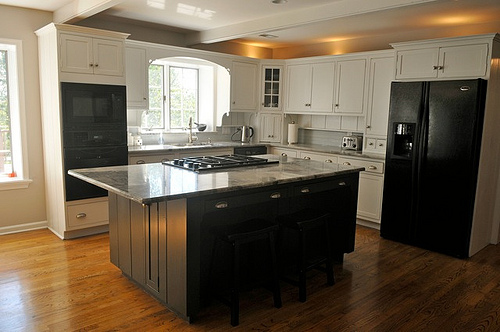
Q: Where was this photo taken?
A: In a kitchen.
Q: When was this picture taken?
A: During the daytime.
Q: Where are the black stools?
A: Under the kitchen island.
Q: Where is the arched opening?
A: Above the window over the sink.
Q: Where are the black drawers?
A: Above the stools.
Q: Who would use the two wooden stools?
A: People sitting at the kitchen island.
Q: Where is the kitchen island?
A: In the middle of the room.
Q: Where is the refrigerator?
A: To the right of the kitchen island.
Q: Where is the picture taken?
A: A kitchen.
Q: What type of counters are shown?
A: Granite.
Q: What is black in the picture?
A: Appliances.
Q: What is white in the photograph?
A: Cabinets.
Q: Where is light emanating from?
A: Windows.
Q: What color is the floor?
A: Tan.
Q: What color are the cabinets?
A: White.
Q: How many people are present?
A: 0.